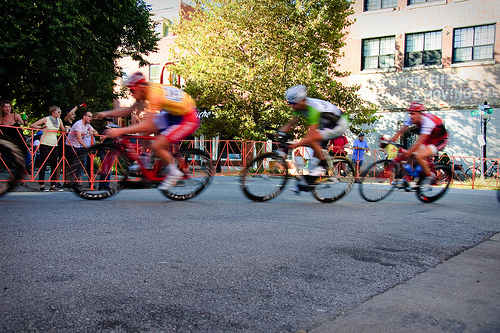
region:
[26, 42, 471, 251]
Three people on bicycles in roadway.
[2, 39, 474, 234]
Three people racing bicycles in roadway.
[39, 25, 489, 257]
Some people on bicycles in roadway.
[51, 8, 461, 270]
Some people racing bicycles in roadway.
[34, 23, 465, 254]
Group of people on bicycles in roadway.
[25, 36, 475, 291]
Group of people racing bicycles in roadway.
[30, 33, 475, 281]
people riding bicycles on roadway.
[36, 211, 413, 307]
cement pavement area in view.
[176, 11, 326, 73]
some green trees in view.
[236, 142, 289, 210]
front wheel of bicycle in motion.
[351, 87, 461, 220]
man riding bike in red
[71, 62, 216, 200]
Man riding bicycle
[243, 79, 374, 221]
man riding bicycle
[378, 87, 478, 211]
man riding bicycle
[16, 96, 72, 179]
woman in yellow shirt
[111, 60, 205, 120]
man in orange shirt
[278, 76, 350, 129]
man in green and black shirt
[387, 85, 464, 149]
man in white, red, and black shirt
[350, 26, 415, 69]
window in building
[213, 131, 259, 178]
red iron railing fence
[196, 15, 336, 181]
tree on the bicycle race route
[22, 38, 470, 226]
bicyclists racing along roadway.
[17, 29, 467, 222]
multiple bicyclists racing along roadway.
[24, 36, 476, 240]
group of bicyclists racing along roadway.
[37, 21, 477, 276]
bicyclists racing on roadway during daytime.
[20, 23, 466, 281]
some bicyclists racing on roadway during daytime.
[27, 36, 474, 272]
multiple bicyclists racing on roadway during daytime.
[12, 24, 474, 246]
several bicyclists racing on roadway during daytime.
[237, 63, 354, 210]
bicyclist wearing helmet while riding.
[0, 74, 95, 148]
some spectators viewing the event.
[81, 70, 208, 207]
man riding bicycle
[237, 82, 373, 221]
man riding cycle on city street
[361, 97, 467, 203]
man riding bicycle on city street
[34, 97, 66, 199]
woman watching bike race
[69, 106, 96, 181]
man watching bike race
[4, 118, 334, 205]
reflective orange safety barrier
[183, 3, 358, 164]
tree with green leaves on city street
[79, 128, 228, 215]
red bike with black race tires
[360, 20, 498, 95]
windows in city building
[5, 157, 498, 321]
asphalt city street